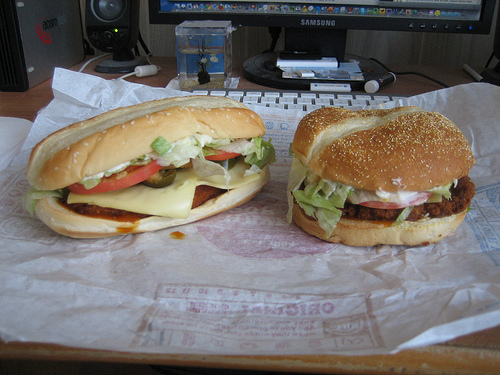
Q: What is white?
A: Wrapper.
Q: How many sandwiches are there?
A: Two.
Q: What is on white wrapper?
A: Sandwiches.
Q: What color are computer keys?
A: White.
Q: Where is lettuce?
A: In both sandwiches.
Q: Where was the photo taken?
A: Desk.